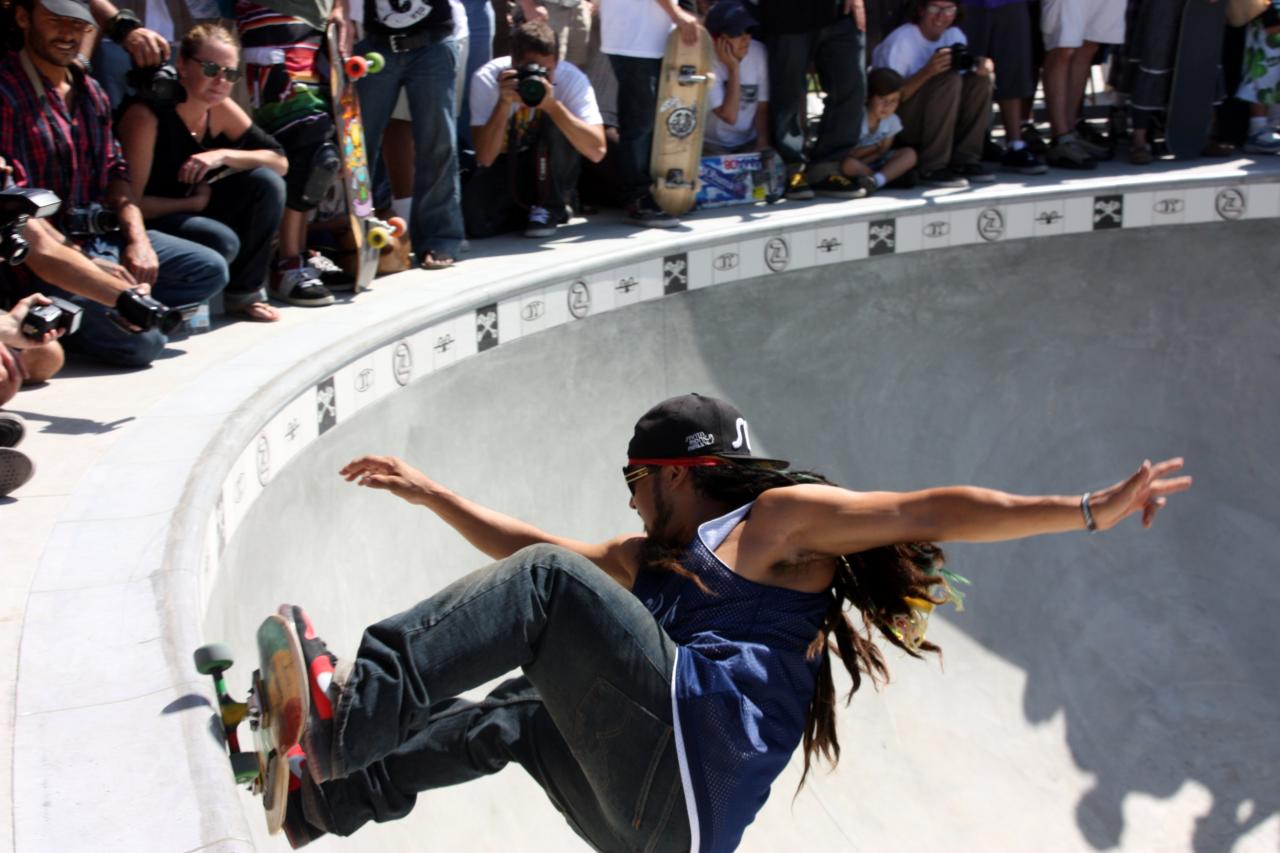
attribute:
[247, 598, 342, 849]
shoes — red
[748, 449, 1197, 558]
arm — extended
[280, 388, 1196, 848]
body — human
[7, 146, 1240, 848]
park — skate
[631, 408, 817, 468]
cap — blue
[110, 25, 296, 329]
woman — sitting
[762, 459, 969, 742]
hair — long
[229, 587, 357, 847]
shoes — red, black